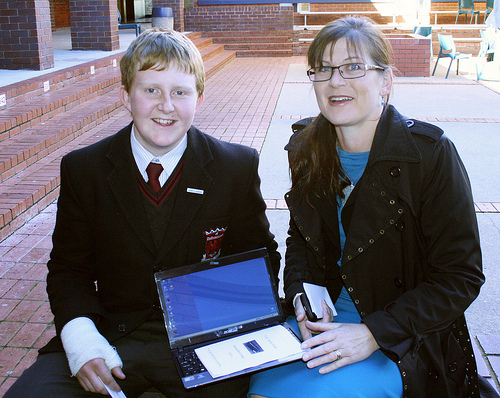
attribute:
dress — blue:
[246, 142, 405, 398]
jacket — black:
[283, 103, 485, 396]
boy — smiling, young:
[4, 27, 282, 397]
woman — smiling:
[247, 16, 485, 398]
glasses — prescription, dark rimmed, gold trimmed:
[306, 62, 385, 84]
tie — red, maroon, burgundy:
[145, 163, 164, 194]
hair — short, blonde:
[119, 28, 205, 97]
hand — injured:
[59, 317, 126, 397]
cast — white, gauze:
[60, 314, 126, 376]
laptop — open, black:
[154, 245, 310, 392]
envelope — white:
[303, 281, 340, 319]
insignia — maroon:
[201, 224, 230, 264]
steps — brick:
[1, 31, 237, 243]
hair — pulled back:
[288, 13, 403, 211]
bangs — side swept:
[306, 29, 369, 68]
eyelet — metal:
[389, 198, 396, 205]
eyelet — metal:
[379, 227, 387, 236]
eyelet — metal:
[345, 253, 354, 262]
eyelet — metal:
[347, 287, 351, 292]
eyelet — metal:
[400, 370, 408, 378]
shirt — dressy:
[130, 122, 189, 188]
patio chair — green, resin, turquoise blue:
[431, 33, 474, 76]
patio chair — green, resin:
[455, 0, 482, 22]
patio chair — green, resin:
[484, 0, 492, 17]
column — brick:
[1, 0, 56, 70]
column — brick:
[69, 0, 120, 51]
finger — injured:
[90, 357, 122, 393]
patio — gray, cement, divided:
[259, 57, 500, 398]